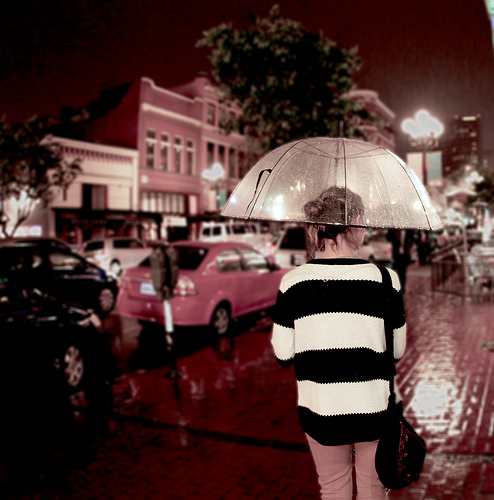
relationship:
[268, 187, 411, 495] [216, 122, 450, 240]
woman holding umbrella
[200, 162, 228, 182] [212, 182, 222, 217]
bulbs on pole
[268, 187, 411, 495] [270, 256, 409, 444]
woman wearing sweater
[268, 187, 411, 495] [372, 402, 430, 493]
woman carrying purse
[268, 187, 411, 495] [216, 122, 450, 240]
woman carrying umbrella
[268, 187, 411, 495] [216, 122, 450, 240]
woman using umbrella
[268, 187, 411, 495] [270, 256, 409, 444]
woman wears sweater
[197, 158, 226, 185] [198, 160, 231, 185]
top of bulbs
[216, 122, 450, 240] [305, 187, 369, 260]
umbrella over head